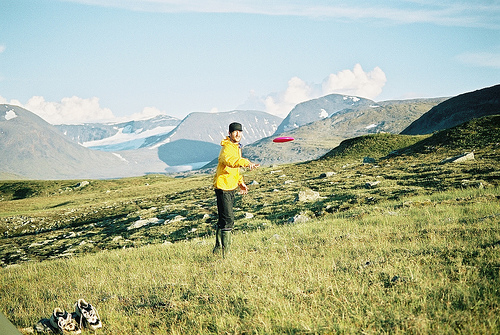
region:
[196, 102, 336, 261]
man throwing a frisbee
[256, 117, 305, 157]
a pink frisbee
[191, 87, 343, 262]
man playing frisbee on a hill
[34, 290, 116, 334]
a pair of white and black sneakers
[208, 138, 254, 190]
man wearing a yellow sweater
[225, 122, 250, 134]
man wearing a black hat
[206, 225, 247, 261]
man wearing high boots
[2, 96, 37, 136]
snow on top of a mountain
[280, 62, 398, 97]
fluffy white clouds in the sky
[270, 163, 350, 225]
a bunch of rocks on the grass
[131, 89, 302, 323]
the man in yellow jacket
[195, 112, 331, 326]
the man in yellow jacket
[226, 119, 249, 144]
the head of a man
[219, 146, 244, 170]
the arm of a man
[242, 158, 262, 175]
the hand of a man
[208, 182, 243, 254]
the legs of a man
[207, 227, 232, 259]
a pair of black boots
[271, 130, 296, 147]
a purple Frisbee in the air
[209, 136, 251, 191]
a yellow hoodie on the man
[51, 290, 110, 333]
a pair of white shoes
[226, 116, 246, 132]
a black hat on the man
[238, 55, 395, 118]
a white cloud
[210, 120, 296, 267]
man throwing frisbee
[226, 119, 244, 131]
black cap on man's head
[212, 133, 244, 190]
bright yellow hooded sweatshirt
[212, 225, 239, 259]
olive green muck boots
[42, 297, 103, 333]
untied tennis shoes in grass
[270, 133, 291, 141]
red frisbee in mid-flight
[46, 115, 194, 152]
melting snow on mountains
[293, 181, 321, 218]
boulders jutting from hillside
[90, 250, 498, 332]
fresh grass on hillside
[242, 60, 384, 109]
tufty clouds in sky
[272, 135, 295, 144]
a flying red frisbee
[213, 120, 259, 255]
a man in a yellow jacket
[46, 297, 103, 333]
a pair of sneakers on the grass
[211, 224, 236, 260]
man is wearing tall boots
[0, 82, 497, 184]
mountains with snow behind the man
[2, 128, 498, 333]
green rolling hills with rocks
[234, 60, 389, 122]
white clouds in the background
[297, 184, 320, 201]
a rock in the green fields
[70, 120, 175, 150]
a large patch of snow on the mountain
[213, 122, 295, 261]
a man throwing a frisbee